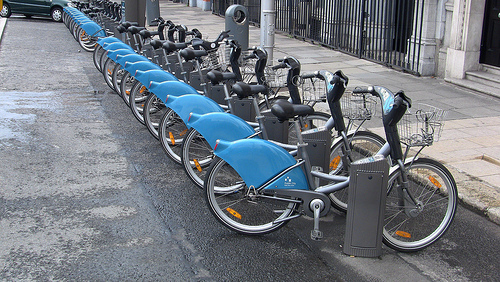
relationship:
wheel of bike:
[204, 152, 301, 232] [216, 83, 458, 253]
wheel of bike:
[93, 45, 110, 73] [93, 17, 163, 72]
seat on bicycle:
[271, 99, 314, 124] [197, 82, 477, 253]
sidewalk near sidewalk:
[0, 0, 498, 282] [166, 6, 498, 250]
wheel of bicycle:
[382, 158, 458, 252] [270, 109, 432, 210]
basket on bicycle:
[395, 100, 445, 146] [197, 82, 477, 253]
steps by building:
[417, 36, 499, 107] [181, 1, 499, 95]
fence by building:
[171, 0, 425, 75] [161, 0, 491, 101]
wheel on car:
[0, 6, 63, 21] [0, 0, 65, 22]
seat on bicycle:
[266, 95, 316, 123] [179, 64, 346, 196]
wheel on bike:
[378, 156, 457, 252] [167, 77, 469, 259]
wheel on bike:
[382, 158, 458, 252] [356, 75, 460, 250]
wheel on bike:
[180, 127, 244, 195] [181, 67, 348, 148]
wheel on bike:
[155, 101, 212, 168] [156, 58, 326, 168]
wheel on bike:
[144, 85, 159, 145] [216, 83, 458, 253]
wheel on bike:
[127, 80, 175, 125] [217, 94, 447, 244]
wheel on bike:
[382, 158, 458, 252] [216, 83, 458, 253]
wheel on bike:
[203, 156, 301, 235] [180, 69, 396, 216]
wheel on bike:
[178, 118, 241, 195] [162, 57, 343, 171]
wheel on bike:
[158, 108, 212, 168] [145, 43, 309, 141]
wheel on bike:
[129, 80, 178, 128] [126, 44, 255, 126]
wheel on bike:
[76, 18, 103, 53] [190, 79, 455, 248]